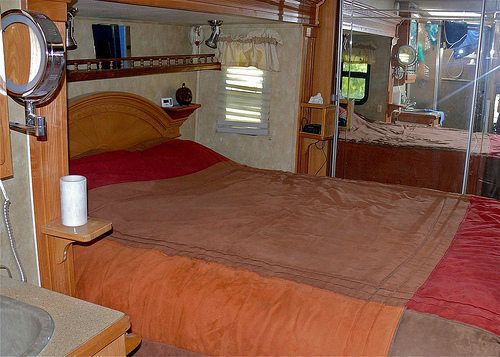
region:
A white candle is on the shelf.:
[42, 174, 114, 246]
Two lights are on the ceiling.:
[63, 6, 231, 48]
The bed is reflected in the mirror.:
[196, 95, 498, 195]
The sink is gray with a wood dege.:
[0, 272, 130, 353]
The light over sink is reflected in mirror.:
[6, 9, 417, 139]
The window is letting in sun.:
[216, 35, 269, 137]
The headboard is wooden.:
[68, 87, 203, 166]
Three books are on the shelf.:
[91, 20, 221, 72]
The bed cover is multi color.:
[65, 135, 498, 355]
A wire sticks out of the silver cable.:
[1, 180, 28, 282]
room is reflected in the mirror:
[333, 2, 499, 196]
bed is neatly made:
[37, 90, 499, 352]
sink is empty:
[2, 271, 146, 353]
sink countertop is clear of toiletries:
[3, 267, 133, 354]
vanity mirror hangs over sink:
[4, 7, 71, 144]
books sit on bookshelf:
[87, 19, 141, 73]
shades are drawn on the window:
[208, 33, 283, 138]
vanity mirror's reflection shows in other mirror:
[390, 43, 417, 85]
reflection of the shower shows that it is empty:
[415, 14, 488, 134]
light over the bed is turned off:
[201, 13, 225, 51]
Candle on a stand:
[54, 173, 101, 230]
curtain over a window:
[205, 42, 279, 157]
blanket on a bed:
[116, 120, 431, 347]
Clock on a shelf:
[144, 90, 185, 115]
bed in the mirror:
[365, 63, 495, 200]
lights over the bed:
[176, 20, 248, 68]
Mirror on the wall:
[3, 6, 93, 136]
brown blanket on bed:
[126, 140, 451, 311]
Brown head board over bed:
[66, 73, 217, 169]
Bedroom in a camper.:
[12, 5, 493, 348]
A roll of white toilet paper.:
[48, 170, 104, 227]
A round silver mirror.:
[5, 3, 76, 133]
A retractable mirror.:
[1, 2, 73, 147]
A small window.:
[206, 28, 279, 139]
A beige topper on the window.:
[199, 30, 284, 70]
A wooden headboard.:
[64, 88, 193, 165]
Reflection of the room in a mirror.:
[331, 9, 499, 194]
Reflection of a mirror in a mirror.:
[387, 33, 420, 83]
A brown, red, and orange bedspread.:
[87, 129, 497, 353]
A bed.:
[61, 87, 498, 348]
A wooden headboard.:
[66, 95, 184, 162]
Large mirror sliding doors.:
[334, 1, 499, 201]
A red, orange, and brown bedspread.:
[71, 136, 498, 353]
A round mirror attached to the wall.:
[2, 7, 67, 136]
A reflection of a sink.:
[401, 91, 440, 126]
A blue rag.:
[426, 104, 448, 127]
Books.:
[92, 20, 133, 69]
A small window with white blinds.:
[214, 29, 271, 136]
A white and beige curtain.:
[213, 32, 281, 69]